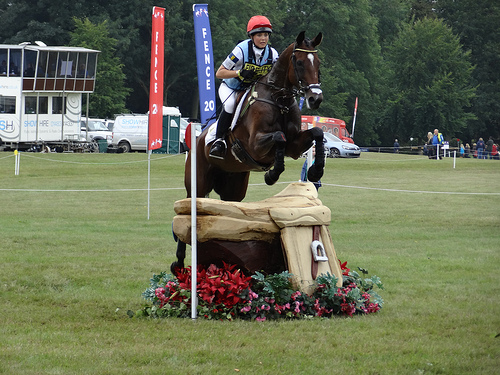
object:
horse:
[169, 32, 326, 285]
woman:
[217, 15, 280, 160]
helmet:
[246, 15, 274, 34]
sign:
[191, 2, 217, 130]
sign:
[150, 5, 163, 151]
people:
[426, 129, 445, 160]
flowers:
[139, 263, 382, 318]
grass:
[1, 151, 499, 374]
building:
[0, 42, 100, 152]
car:
[314, 129, 360, 159]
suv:
[301, 114, 362, 159]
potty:
[152, 106, 181, 154]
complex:
[172, 181, 348, 294]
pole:
[188, 121, 199, 320]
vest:
[223, 40, 279, 90]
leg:
[292, 126, 325, 182]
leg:
[249, 104, 287, 186]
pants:
[218, 81, 238, 115]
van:
[111, 114, 205, 152]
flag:
[13, 149, 19, 155]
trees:
[1, 0, 499, 152]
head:
[280, 30, 323, 110]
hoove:
[306, 166, 324, 182]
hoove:
[264, 169, 279, 186]